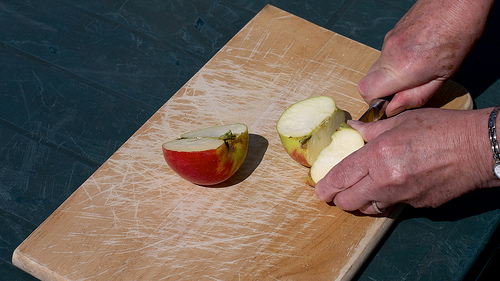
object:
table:
[0, 0, 497, 281]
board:
[11, 28, 474, 281]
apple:
[161, 124, 248, 185]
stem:
[222, 132, 238, 158]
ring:
[366, 202, 385, 214]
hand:
[312, 107, 477, 215]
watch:
[486, 112, 499, 160]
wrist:
[471, 106, 497, 184]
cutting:
[278, 88, 404, 185]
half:
[274, 97, 346, 169]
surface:
[276, 95, 337, 137]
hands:
[340, 44, 451, 185]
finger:
[348, 188, 405, 215]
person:
[314, 0, 500, 217]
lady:
[376, 46, 464, 196]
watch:
[485, 105, 500, 183]